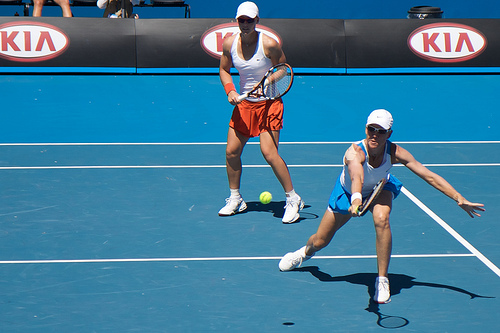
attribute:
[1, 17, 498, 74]
barrier — black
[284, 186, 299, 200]
sock — white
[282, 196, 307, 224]
shoe — white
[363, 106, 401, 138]
hat — white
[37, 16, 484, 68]
wall — black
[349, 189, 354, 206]
wrist band — orange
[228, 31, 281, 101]
tank top — white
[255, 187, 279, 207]
ball — green 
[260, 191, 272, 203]
ball — in the air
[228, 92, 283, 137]
skirt — orange 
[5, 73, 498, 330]
court — blue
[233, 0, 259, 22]
hat — white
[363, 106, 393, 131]
hat — white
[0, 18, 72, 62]
logo — for KIA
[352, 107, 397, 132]
hat — white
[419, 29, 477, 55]
kia — written in red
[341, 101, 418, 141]
hat — white 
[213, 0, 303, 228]
people — playing tennis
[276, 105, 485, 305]
people — playing tennis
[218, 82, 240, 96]
wrist band — orange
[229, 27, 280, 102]
shirt — white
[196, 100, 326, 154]
shorts — orange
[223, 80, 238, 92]
wristband — orange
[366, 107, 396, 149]
head — mans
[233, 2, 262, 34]
head — mans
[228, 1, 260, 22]
hat — white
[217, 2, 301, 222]
person — playing tennis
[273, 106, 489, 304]
person — playing tennis